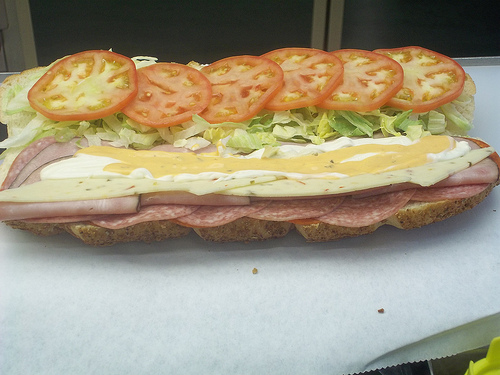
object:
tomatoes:
[25, 49, 135, 125]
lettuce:
[56, 115, 446, 138]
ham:
[9, 193, 478, 218]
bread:
[3, 135, 496, 247]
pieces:
[0, 183, 140, 221]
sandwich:
[0, 32, 498, 242]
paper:
[0, 59, 498, 374]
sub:
[0, 48, 497, 260]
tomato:
[116, 61, 213, 129]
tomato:
[196, 54, 282, 124]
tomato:
[260, 47, 343, 112]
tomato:
[314, 47, 402, 112]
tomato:
[367, 34, 465, 113]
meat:
[2, 137, 500, 225]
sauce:
[17, 134, 470, 165]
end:
[387, 45, 496, 230]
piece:
[0, 141, 185, 210]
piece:
[136, 173, 281, 198]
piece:
[374, 134, 492, 188]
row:
[32, 46, 463, 124]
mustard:
[43, 134, 468, 182]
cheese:
[0, 144, 495, 201]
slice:
[12, 143, 139, 216]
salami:
[2, 187, 140, 221]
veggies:
[10, 55, 465, 133]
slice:
[29, 47, 143, 127]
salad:
[4, 70, 467, 148]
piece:
[230, 147, 412, 198]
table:
[6, 55, 499, 375]